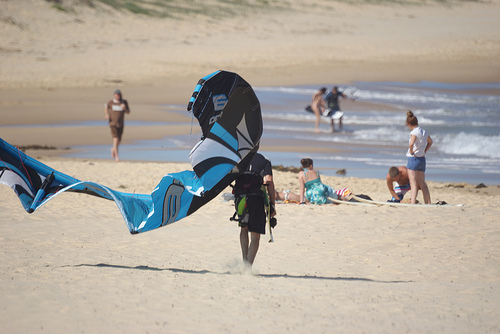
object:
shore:
[0, 158, 500, 334]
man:
[104, 89, 131, 163]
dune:
[0, 0, 499, 70]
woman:
[311, 88, 326, 133]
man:
[322, 85, 347, 134]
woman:
[298, 158, 336, 205]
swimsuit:
[303, 168, 330, 205]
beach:
[0, 0, 499, 333]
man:
[226, 140, 277, 270]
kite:
[1, 69, 264, 235]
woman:
[406, 109, 434, 204]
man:
[386, 166, 411, 203]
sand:
[0, 162, 498, 330]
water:
[442, 83, 496, 165]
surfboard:
[303, 105, 342, 118]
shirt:
[405, 126, 429, 158]